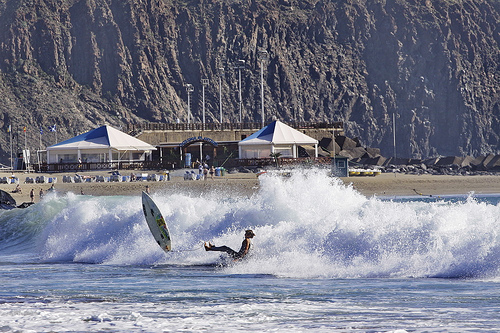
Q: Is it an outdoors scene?
A: Yes, it is outdoors.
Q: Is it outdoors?
A: Yes, it is outdoors.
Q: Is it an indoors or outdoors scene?
A: It is outdoors.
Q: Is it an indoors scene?
A: No, it is outdoors.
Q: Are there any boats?
A: No, there are no boats.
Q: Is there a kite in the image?
A: No, there are no kites.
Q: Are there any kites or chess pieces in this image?
A: No, there are no kites or chess pieces.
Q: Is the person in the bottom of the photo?
A: Yes, the person is in the bottom of the image.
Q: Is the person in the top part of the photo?
A: No, the person is in the bottom of the image.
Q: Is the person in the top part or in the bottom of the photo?
A: The person is in the bottom of the image.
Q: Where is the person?
A: The person is in the water.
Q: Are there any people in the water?
A: Yes, there is a person in the water.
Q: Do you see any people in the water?
A: Yes, there is a person in the water.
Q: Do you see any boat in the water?
A: No, there is a person in the water.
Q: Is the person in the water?
A: Yes, the person is in the water.